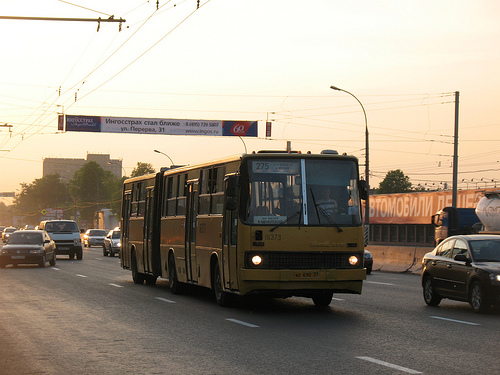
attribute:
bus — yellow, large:
[115, 153, 368, 301]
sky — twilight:
[282, 24, 309, 48]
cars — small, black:
[13, 226, 115, 274]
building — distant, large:
[32, 149, 132, 172]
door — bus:
[221, 192, 243, 283]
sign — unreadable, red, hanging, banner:
[166, 116, 222, 136]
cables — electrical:
[87, 32, 198, 53]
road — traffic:
[96, 325, 211, 350]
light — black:
[316, 77, 342, 105]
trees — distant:
[66, 169, 118, 198]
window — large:
[183, 172, 226, 204]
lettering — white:
[344, 197, 379, 205]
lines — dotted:
[372, 362, 383, 364]